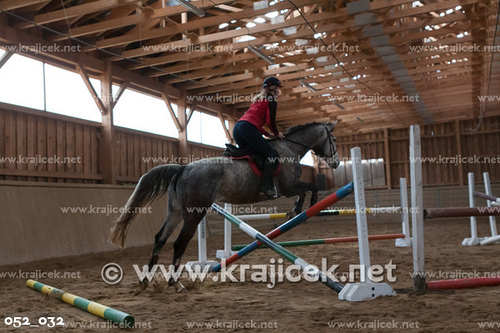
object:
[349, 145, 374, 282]
white pole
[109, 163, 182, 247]
tail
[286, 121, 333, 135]
mane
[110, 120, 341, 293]
horse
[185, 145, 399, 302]
structure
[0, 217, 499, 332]
dirt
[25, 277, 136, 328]
pole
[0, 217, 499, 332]
ground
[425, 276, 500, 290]
pole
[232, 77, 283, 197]
girl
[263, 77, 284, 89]
hat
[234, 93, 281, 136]
shirt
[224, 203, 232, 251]
pole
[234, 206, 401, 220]
pole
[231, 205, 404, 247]
frame